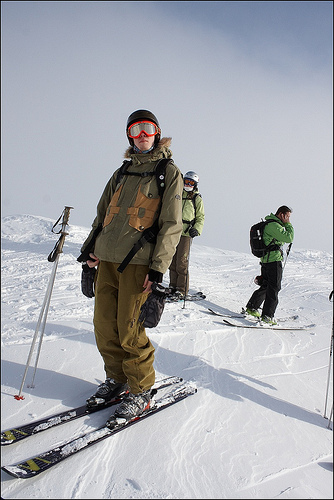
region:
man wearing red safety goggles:
[83, 91, 169, 426]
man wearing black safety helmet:
[70, 94, 189, 428]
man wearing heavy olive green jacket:
[62, 105, 206, 421]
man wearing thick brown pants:
[70, 108, 200, 437]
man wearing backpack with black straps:
[81, 102, 202, 432]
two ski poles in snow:
[11, 191, 75, 408]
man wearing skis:
[3, 73, 215, 497]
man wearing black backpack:
[219, 189, 312, 345]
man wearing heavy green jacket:
[221, 192, 314, 339]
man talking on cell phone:
[224, 184, 315, 336]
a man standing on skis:
[7, 108, 195, 472]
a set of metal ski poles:
[13, 203, 72, 400]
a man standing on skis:
[207, 205, 315, 331]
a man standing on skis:
[148, 167, 210, 302]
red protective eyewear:
[124, 120, 158, 139]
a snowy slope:
[2, 213, 329, 497]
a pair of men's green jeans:
[90, 262, 156, 393]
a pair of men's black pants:
[246, 259, 283, 317]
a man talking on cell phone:
[240, 201, 295, 327]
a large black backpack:
[247, 217, 284, 258]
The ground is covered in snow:
[3, 214, 327, 498]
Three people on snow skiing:
[55, 106, 309, 451]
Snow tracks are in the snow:
[6, 220, 139, 346]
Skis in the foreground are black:
[4, 361, 201, 496]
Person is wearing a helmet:
[108, 99, 179, 166]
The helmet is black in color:
[116, 99, 169, 161]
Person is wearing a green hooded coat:
[252, 202, 299, 266]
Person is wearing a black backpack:
[246, 217, 276, 261]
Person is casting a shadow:
[25, 302, 332, 444]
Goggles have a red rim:
[118, 113, 167, 143]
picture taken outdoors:
[26, 227, 322, 455]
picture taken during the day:
[43, 223, 322, 478]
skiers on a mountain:
[54, 245, 320, 472]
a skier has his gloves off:
[63, 240, 241, 383]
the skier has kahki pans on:
[84, 253, 191, 458]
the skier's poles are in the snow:
[23, 227, 107, 408]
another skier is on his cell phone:
[264, 204, 318, 335]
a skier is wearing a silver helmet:
[182, 148, 216, 229]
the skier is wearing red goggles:
[110, 130, 161, 171]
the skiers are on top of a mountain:
[30, 190, 314, 334]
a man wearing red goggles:
[114, 110, 166, 167]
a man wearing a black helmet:
[118, 101, 168, 162]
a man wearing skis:
[64, 96, 184, 484]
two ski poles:
[9, 195, 69, 404]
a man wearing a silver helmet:
[179, 168, 201, 195]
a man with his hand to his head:
[245, 199, 304, 282]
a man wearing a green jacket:
[242, 177, 312, 281]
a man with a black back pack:
[240, 204, 300, 284]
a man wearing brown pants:
[176, 167, 203, 307]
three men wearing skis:
[69, 177, 298, 490]